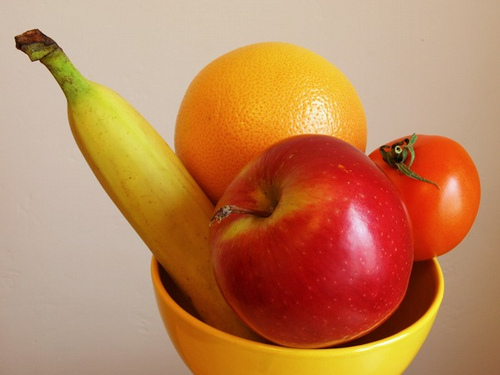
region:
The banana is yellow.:
[8, 24, 253, 352]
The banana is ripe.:
[13, 24, 270, 348]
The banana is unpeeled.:
[9, 20, 257, 362]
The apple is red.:
[197, 126, 424, 347]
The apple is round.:
[196, 129, 422, 351]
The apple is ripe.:
[200, 127, 422, 363]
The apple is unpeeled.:
[197, 117, 419, 368]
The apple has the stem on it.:
[188, 115, 419, 355]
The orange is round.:
[167, 14, 372, 226]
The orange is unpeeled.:
[164, 31, 371, 226]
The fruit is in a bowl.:
[11, 18, 482, 373]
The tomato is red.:
[361, 126, 486, 266]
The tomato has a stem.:
[359, 115, 484, 267]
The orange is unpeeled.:
[171, 31, 373, 235]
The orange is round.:
[166, 36, 371, 213]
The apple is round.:
[200, 130, 420, 357]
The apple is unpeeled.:
[204, 128, 416, 349]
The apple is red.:
[201, 132, 418, 352]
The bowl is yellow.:
[131, 228, 455, 374]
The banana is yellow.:
[13, 28, 272, 357]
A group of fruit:
[6, 12, 485, 363]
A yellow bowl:
[153, 275, 455, 373]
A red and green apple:
[213, 140, 415, 342]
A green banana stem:
[16, 33, 101, 109]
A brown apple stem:
[207, 179, 264, 240]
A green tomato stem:
[383, 135, 429, 183]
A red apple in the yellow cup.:
[237, 166, 381, 319]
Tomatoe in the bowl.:
[363, 115, 487, 258]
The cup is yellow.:
[133, 283, 461, 367]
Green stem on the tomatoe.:
[368, 137, 423, 182]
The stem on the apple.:
[192, 180, 270, 227]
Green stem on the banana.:
[19, 27, 67, 73]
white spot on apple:
[324, 216, 331, 224]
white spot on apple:
[268, 295, 275, 302]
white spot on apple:
[281, 313, 288, 319]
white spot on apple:
[303, 282, 314, 292]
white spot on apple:
[326, 303, 331, 310]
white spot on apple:
[379, 227, 386, 237]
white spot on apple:
[356, 253, 365, 261]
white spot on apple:
[374, 271, 381, 283]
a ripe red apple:
[195, 121, 424, 342]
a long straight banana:
[33, 34, 230, 304]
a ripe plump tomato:
[362, 113, 487, 269]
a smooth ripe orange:
[158, 36, 393, 187]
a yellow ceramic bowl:
[126, 240, 461, 369]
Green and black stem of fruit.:
[18, 28, 81, 93]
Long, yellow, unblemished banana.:
[12, 20, 213, 307]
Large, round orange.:
[172, 46, 371, 186]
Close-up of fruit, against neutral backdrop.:
[0, 8, 488, 372]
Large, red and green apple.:
[210, 152, 408, 330]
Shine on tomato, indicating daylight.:
[441, 172, 463, 210]